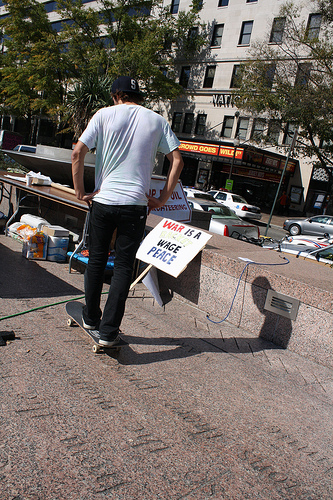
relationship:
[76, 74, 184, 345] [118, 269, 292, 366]
man casting shadow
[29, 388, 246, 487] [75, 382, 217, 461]
ground has prints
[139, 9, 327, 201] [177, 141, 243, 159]
building has sign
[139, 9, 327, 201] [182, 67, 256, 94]
building has black windows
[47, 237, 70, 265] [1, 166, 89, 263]
paper towels are under table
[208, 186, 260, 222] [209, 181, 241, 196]
police car has top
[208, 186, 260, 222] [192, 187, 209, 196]
police car has hood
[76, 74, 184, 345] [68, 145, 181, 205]
guy has hands on hips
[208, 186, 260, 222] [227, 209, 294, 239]
police car in roadway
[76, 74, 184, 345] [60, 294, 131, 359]
man standing on skateboard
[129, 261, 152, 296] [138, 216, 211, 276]
pole has protest sign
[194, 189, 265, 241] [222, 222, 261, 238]
car has brake lights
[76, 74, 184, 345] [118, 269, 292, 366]
skateboarder has shadow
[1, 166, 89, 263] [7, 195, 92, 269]
table has legs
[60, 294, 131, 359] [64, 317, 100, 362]
skateboard has wheels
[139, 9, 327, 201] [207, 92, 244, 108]
building has letters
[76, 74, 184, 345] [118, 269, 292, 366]
man has shadow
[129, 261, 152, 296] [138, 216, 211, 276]
stick has protest sign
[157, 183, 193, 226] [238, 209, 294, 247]
sign beside roadway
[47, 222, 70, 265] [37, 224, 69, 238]
containers are for storage